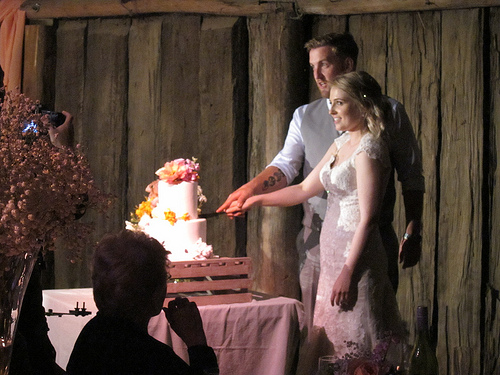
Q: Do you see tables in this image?
A: Yes, there is a table.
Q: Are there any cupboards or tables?
A: Yes, there is a table.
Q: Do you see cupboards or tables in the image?
A: Yes, there is a table.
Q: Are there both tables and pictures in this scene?
A: No, there is a table but no pictures.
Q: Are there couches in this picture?
A: No, there are no couches.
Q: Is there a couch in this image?
A: No, there are no couches.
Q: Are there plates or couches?
A: No, there are no couches or plates.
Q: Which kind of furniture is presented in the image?
A: The furniture is a table.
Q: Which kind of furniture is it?
A: The piece of furniture is a table.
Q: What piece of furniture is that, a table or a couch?
A: This is a table.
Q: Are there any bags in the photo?
A: No, there are no bags.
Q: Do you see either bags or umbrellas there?
A: No, there are no bags or umbrellas.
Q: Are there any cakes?
A: Yes, there is a cake.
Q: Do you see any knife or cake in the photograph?
A: Yes, there is a cake.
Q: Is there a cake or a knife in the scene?
A: Yes, there is a cake.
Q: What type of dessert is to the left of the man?
A: The dessert is a cake.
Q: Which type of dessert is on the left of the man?
A: The dessert is a cake.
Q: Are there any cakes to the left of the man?
A: Yes, there is a cake to the left of the man.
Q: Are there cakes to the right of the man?
A: No, the cake is to the left of the man.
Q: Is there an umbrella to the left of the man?
A: No, there is a cake to the left of the man.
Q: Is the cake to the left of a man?
A: Yes, the cake is to the left of a man.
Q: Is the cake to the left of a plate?
A: No, the cake is to the left of a man.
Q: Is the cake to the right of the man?
A: No, the cake is to the left of the man.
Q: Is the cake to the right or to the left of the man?
A: The cake is to the left of the man.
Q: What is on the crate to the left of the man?
A: The cake is on the crate.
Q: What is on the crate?
A: The cake is on the crate.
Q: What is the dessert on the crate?
A: The dessert is a cake.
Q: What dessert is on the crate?
A: The dessert is a cake.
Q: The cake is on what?
A: The cake is on the crate.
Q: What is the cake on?
A: The cake is on the crate.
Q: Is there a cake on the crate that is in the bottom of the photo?
A: Yes, there is a cake on the crate.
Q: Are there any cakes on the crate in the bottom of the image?
A: Yes, there is a cake on the crate.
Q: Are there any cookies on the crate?
A: No, there is a cake on the crate.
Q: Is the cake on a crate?
A: Yes, the cake is on a crate.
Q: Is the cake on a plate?
A: No, the cake is on a crate.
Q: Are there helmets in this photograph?
A: No, there are no helmets.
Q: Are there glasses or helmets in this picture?
A: No, there are no helmets or glasses.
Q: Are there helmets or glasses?
A: No, there are no helmets or glasses.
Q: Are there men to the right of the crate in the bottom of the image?
A: Yes, there is a man to the right of the crate.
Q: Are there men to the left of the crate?
A: No, the man is to the right of the crate.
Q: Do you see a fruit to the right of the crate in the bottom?
A: No, there is a man to the right of the crate.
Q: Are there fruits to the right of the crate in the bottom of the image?
A: No, there is a man to the right of the crate.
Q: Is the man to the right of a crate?
A: Yes, the man is to the right of a crate.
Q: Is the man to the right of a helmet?
A: No, the man is to the right of a crate.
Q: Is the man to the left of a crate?
A: No, the man is to the right of a crate.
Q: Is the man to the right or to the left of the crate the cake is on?
A: The man is to the right of the crate.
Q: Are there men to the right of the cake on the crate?
A: Yes, there is a man to the right of the cake.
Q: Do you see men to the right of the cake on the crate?
A: Yes, there is a man to the right of the cake.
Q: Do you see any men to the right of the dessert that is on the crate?
A: Yes, there is a man to the right of the cake.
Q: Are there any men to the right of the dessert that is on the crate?
A: Yes, there is a man to the right of the cake.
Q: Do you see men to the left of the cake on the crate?
A: No, the man is to the right of the cake.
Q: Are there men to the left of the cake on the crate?
A: No, the man is to the right of the cake.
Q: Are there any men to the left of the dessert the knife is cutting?
A: No, the man is to the right of the cake.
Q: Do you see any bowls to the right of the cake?
A: No, there is a man to the right of the cake.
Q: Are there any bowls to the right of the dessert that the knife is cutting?
A: No, there is a man to the right of the cake.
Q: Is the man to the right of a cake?
A: Yes, the man is to the right of a cake.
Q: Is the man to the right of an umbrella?
A: No, the man is to the right of a cake.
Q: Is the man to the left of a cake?
A: No, the man is to the right of a cake.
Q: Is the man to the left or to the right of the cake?
A: The man is to the right of the cake.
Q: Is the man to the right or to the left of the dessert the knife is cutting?
A: The man is to the right of the cake.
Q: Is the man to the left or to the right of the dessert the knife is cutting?
A: The man is to the right of the cake.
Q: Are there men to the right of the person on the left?
A: Yes, there is a man to the right of the person.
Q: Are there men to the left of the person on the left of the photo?
A: No, the man is to the right of the person.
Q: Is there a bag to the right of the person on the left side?
A: No, there is a man to the right of the person.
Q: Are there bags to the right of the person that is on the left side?
A: No, there is a man to the right of the person.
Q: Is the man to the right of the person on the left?
A: Yes, the man is to the right of the person.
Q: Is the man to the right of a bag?
A: No, the man is to the right of the person.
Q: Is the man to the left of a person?
A: No, the man is to the right of a person.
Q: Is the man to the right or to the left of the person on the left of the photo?
A: The man is to the right of the person.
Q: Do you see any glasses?
A: No, there are no glasses.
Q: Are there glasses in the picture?
A: No, there are no glasses.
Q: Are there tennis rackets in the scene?
A: No, there are no tennis rackets.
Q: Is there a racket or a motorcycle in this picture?
A: No, there are no rackets or motorcycles.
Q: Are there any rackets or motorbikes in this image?
A: No, there are no rackets or motorbikes.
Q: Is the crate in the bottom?
A: Yes, the crate is in the bottom of the image.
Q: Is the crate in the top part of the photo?
A: No, the crate is in the bottom of the image.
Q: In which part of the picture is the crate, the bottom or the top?
A: The crate is in the bottom of the image.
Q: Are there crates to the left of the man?
A: Yes, there is a crate to the left of the man.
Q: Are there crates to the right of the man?
A: No, the crate is to the left of the man.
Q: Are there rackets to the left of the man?
A: No, there is a crate to the left of the man.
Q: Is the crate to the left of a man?
A: Yes, the crate is to the left of a man.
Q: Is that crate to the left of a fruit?
A: No, the crate is to the left of a man.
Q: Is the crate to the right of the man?
A: No, the crate is to the left of the man.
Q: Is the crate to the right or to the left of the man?
A: The crate is to the left of the man.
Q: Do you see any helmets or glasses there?
A: No, there are no glasses or helmets.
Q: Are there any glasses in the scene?
A: No, there are no glasses.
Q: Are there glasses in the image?
A: No, there are no glasses.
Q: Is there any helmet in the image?
A: No, there are no helmets.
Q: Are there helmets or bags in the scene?
A: No, there are no helmets or bags.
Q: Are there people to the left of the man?
A: Yes, there is a person to the left of the man.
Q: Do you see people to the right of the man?
A: No, the person is to the left of the man.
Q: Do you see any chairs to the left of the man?
A: No, there is a person to the left of the man.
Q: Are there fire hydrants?
A: No, there are no fire hydrants.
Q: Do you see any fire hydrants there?
A: No, there are no fire hydrants.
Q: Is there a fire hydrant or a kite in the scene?
A: No, there are no fire hydrants or kites.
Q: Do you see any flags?
A: No, there are no flags.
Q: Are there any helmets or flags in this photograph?
A: No, there are no flags or helmets.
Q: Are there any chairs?
A: No, there are no chairs.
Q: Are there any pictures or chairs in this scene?
A: No, there are no chairs or pictures.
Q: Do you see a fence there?
A: Yes, there is a fence.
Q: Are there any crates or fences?
A: Yes, there is a fence.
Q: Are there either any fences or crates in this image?
A: Yes, there is a fence.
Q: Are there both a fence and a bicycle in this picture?
A: No, there is a fence but no bicycles.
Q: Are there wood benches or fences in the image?
A: Yes, there is a wood fence.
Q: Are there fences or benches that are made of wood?
A: Yes, the fence is made of wood.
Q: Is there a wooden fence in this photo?
A: Yes, there is a wood fence.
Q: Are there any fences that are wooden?
A: Yes, there is a wood fence.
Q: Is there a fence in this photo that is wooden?
A: Yes, there is a fence that is wooden.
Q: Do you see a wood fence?
A: Yes, there is a fence that is made of wood.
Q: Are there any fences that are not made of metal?
A: Yes, there is a fence that is made of wood.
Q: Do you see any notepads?
A: No, there are no notepads.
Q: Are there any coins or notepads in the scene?
A: No, there are no notepads or coins.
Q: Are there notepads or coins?
A: No, there are no notepads or coins.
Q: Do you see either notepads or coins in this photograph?
A: No, there are no notepads or coins.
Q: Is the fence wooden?
A: Yes, the fence is wooden.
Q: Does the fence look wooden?
A: Yes, the fence is wooden.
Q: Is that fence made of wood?
A: Yes, the fence is made of wood.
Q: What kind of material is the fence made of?
A: The fence is made of wood.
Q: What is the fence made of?
A: The fence is made of wood.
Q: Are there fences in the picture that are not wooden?
A: No, there is a fence but it is wooden.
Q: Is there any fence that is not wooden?
A: No, there is a fence but it is wooden.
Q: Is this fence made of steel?
A: No, the fence is made of wood.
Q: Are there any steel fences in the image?
A: No, there is a fence but it is made of wood.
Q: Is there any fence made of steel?
A: No, there is a fence but it is made of wood.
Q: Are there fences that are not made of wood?
A: No, there is a fence but it is made of wood.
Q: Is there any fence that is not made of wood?
A: No, there is a fence but it is made of wood.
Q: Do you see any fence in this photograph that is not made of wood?
A: No, there is a fence but it is made of wood.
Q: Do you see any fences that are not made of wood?
A: No, there is a fence but it is made of wood.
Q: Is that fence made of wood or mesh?
A: The fence is made of wood.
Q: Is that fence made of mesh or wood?
A: The fence is made of wood.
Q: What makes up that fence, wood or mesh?
A: The fence is made of wood.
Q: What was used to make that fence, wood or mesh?
A: The fence is made of wood.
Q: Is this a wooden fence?
A: Yes, this is a wooden fence.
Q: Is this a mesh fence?
A: No, this is a wooden fence.